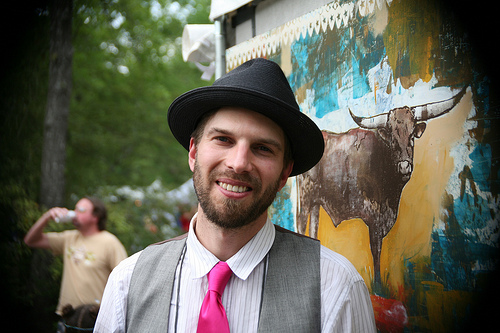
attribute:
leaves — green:
[70, 56, 146, 159]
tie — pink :
[198, 270, 226, 332]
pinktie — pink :
[196, 260, 233, 331]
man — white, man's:
[201, 80, 322, 265]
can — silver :
[53, 205, 80, 230]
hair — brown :
[87, 195, 109, 233]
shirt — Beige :
[46, 230, 128, 309]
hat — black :
[158, 57, 331, 179]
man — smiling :
[92, 55, 382, 330]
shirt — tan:
[101, 208, 394, 328]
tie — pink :
[195, 260, 232, 331]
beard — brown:
[190, 142, 284, 228]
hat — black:
[168, 55, 327, 177]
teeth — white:
[216, 171, 265, 205]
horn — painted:
[342, 104, 387, 135]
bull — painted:
[295, 83, 473, 285]